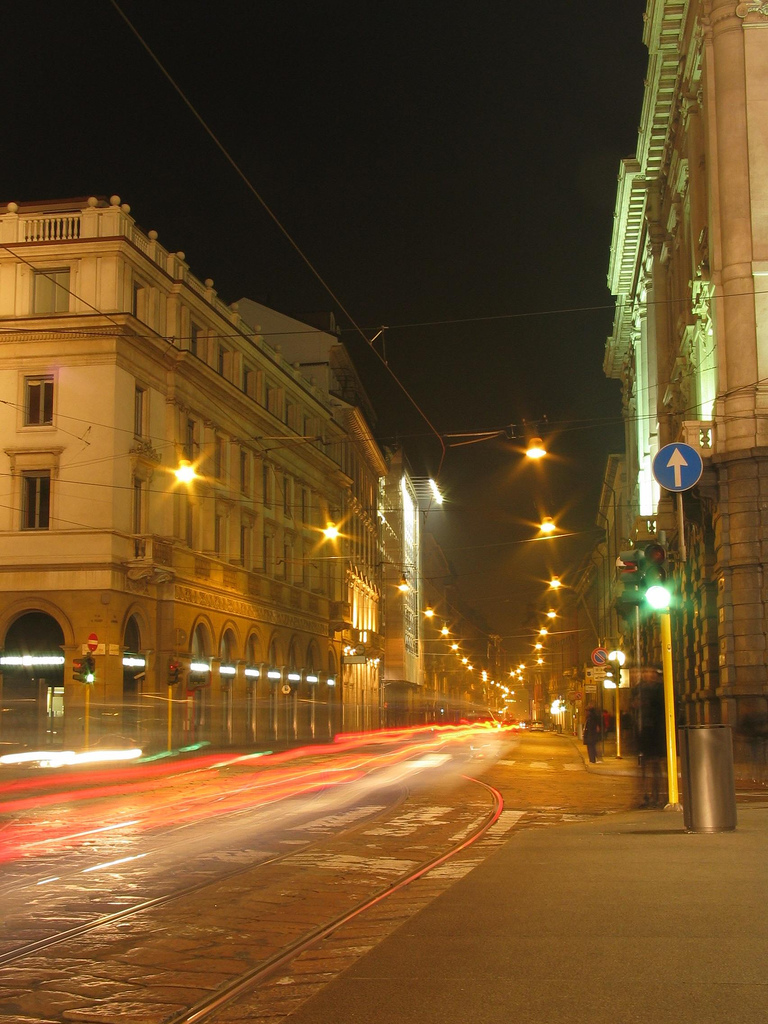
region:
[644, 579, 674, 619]
A green traffic light on the sidewalk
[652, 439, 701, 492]
A blue street sign in the city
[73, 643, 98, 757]
A stoplight on a pole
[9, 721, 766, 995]
Streets in a city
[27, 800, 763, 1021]
A sidewalk in a city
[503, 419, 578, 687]
Street lights in a city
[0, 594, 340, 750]
Archways on a building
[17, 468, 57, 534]
A window on a building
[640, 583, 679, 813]
A green light is on a pole.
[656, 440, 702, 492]
An arrow points straight ahead.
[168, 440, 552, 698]
Street lights are on above the street.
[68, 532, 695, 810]
Traffic signals are on both sides of the street.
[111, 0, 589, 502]
Overhead wires are in the air.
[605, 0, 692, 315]
The roof trim has notches on it.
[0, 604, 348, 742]
Archways are on the building.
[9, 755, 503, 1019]
Rails are on the street.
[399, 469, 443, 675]
White lights shine down on a wall.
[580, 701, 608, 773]
A woman is standing on a curb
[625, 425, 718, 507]
An arrow point upwards sign.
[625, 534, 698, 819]
A street lamp.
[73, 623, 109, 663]
Do not enter sign.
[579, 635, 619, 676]
No access sign.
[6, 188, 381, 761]
Building at night.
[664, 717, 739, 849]
Trashcan.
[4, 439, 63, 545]
Window on the side of a building.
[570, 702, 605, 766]
Person waiting on street.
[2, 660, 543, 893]
Motion blur from car taillights.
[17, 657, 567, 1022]
Road at night with train tracks.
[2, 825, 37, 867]
the light is red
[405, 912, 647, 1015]
the sidewalk is dark grey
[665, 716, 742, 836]
the trashcan is grey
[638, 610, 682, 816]
the pole is bright yellow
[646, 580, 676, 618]
the light is green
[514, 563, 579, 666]
the lights are twinkling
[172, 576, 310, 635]
the sign is on the building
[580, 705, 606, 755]
the person is walking